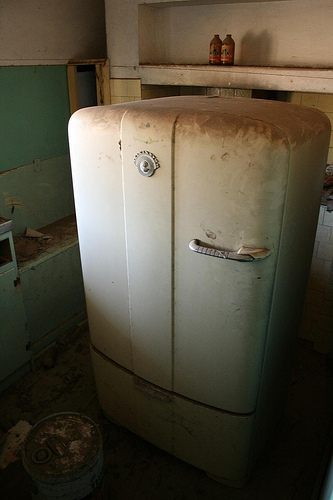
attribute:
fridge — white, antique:
[71, 105, 303, 486]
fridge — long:
[68, 93, 332, 490]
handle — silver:
[187, 238, 272, 261]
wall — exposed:
[2, 63, 72, 164]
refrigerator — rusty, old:
[90, 101, 301, 390]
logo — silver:
[128, 150, 160, 179]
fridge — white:
[84, 73, 294, 298]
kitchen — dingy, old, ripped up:
[3, 0, 331, 498]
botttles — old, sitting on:
[204, 28, 241, 67]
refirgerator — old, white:
[35, 77, 315, 372]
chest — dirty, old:
[66, 94, 330, 480]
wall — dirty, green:
[15, 66, 110, 147]